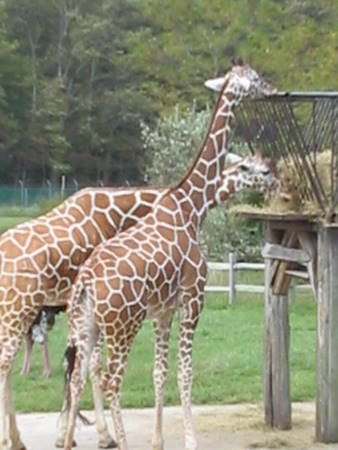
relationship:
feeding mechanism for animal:
[231, 88, 336, 215] [58, 65, 277, 450]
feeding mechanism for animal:
[231, 88, 336, 215] [1, 154, 280, 450]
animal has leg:
[58, 65, 277, 450] [174, 299, 205, 430]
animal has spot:
[58, 65, 277, 450] [149, 270, 169, 290]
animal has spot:
[58, 65, 277, 450] [128, 253, 150, 278]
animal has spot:
[58, 65, 277, 450] [131, 278, 146, 294]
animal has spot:
[58, 65, 277, 450] [119, 278, 137, 302]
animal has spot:
[58, 65, 277, 450] [144, 303, 168, 315]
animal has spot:
[58, 65, 277, 450] [116, 260, 136, 277]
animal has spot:
[58, 65, 277, 450] [95, 251, 113, 262]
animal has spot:
[58, 65, 277, 450] [103, 241, 126, 257]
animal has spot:
[58, 65, 277, 450] [98, 301, 113, 313]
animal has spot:
[41, 39, 285, 351] [140, 241, 155, 253]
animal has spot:
[41, 39, 285, 351] [118, 236, 141, 251]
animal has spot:
[41, 39, 285, 351] [139, 225, 154, 236]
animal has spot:
[41, 39, 285, 351] [115, 233, 134, 239]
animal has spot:
[41, 39, 285, 351] [153, 249, 166, 263]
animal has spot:
[58, 65, 277, 450] [177, 262, 196, 292]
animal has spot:
[58, 65, 277, 450] [198, 262, 209, 276]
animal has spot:
[58, 65, 277, 450] [175, 228, 193, 254]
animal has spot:
[58, 65, 277, 450] [162, 242, 171, 257]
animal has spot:
[58, 65, 277, 450] [152, 251, 169, 266]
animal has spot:
[1, 152, 282, 445] [85, 220, 100, 248]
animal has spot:
[1, 152, 282, 445] [72, 224, 88, 252]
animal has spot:
[1, 152, 282, 445] [69, 206, 84, 222]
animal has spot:
[1, 152, 282, 445] [50, 215, 75, 227]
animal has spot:
[1, 152, 282, 445] [55, 201, 66, 212]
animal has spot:
[1, 154, 280, 450] [13, 229, 31, 247]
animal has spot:
[1, 154, 280, 450] [0, 260, 16, 277]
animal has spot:
[1, 154, 280, 450] [0, 271, 17, 292]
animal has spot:
[1, 154, 280, 450] [31, 248, 49, 271]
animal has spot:
[1, 154, 280, 450] [14, 221, 28, 230]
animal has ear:
[58, 65, 277, 450] [240, 79, 258, 95]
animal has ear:
[58, 65, 277, 450] [202, 77, 229, 94]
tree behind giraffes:
[139, 102, 271, 263] [0, 154, 275, 449]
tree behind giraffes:
[139, 102, 271, 263] [65, 61, 277, 448]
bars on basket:
[229, 102, 328, 206] [233, 84, 338, 224]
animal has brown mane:
[58, 65, 277, 450] [153, 71, 237, 211]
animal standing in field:
[1, 154, 280, 450] [1, 201, 336, 405]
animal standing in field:
[58, 65, 277, 450] [1, 201, 336, 405]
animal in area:
[1, 154, 280, 450] [0, 298, 334, 445]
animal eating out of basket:
[58, 65, 277, 450] [233, 84, 337, 223]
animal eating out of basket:
[1, 154, 280, 450] [233, 84, 337, 223]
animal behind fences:
[58, 65, 277, 450] [206, 240, 275, 306]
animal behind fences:
[1, 154, 280, 450] [11, 177, 321, 224]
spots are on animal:
[231, 82, 246, 93] [58, 65, 277, 450]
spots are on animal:
[254, 80, 267, 92] [58, 65, 277, 450]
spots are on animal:
[101, 257, 120, 277] [1, 152, 282, 445]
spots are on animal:
[239, 172, 267, 189] [1, 152, 282, 445]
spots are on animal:
[72, 268, 97, 296] [1, 152, 282, 445]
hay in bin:
[227, 150, 335, 220] [227, 85, 336, 225]